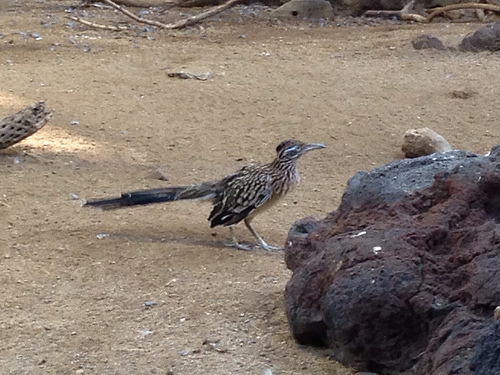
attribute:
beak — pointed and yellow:
[283, 121, 350, 161]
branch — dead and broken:
[68, 1, 290, 36]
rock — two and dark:
[283, 151, 498, 373]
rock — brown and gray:
[271, 170, 498, 344]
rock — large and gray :
[240, 109, 499, 337]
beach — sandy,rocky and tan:
[3, 3, 498, 373]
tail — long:
[82, 181, 218, 211]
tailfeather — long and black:
[79, 177, 222, 212]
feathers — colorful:
[100, 132, 324, 253]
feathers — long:
[84, 172, 209, 232]